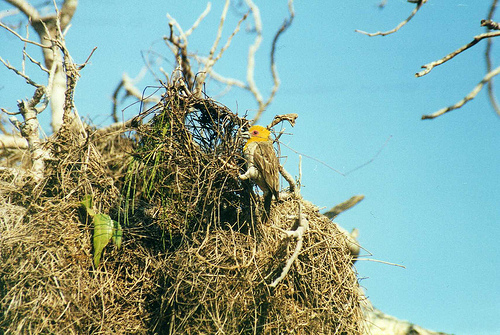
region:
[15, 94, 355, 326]
THAT IS A NEST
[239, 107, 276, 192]
THAT IS A BIRD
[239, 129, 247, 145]
THE BEAK OF THE BIRD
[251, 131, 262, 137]
THE EYE OF THE BIRD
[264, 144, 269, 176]
FEATHERS OF THE BIRD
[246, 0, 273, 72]
A PIECE OF WOOD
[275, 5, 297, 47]
A PIECE OF WOOD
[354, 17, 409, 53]
A PIECE OF WOOD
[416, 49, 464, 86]
A PIECE OF WOOD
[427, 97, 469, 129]
A PIECE OF WOOD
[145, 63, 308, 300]
view is at a bird nest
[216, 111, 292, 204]
bird standing beside the nest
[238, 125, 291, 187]
the bird is brown in color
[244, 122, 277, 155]
the bird has a yelow head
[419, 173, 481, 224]
the sky is clear light blue in color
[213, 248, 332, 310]
the grases are dried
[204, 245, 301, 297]
the grass are brown in color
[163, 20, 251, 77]
the tree branches are dried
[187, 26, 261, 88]
the tree branches are brown in color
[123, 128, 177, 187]
there are green grasses in the dried ones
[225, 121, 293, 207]
bird standing in the grass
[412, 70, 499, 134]
branch with no leaves on it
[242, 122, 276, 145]
bird's head is bright yellow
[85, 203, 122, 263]
bright green leaf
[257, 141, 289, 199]
dark feathers on the body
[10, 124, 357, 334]
a clump of dead grass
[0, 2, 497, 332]
bright blue sky with no clouds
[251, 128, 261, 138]
small black eye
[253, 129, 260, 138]
eye on the side of the head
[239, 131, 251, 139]
small pointy beak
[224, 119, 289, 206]
A yellow bird sits in a nest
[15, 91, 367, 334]
The nest of a bird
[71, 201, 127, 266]
A green leaf in the nest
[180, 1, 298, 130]
A tree stands behind the nest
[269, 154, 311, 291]
A tree branch located in the nest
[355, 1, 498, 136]
Tree branches from a nearby tree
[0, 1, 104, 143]
A tree next to other trees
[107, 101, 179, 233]
Green grass in the nest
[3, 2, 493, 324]
The blue sky above the nest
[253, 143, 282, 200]
The wing of the bird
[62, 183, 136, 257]
leaf on a bunch of grass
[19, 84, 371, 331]
a bunch of weed grass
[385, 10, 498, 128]
tree stick of a tree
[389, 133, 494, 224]
a clear blue sky with no clouds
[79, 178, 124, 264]
some leaves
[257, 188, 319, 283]
tree stick branch on weed grass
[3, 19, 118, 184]
bunch of tree branches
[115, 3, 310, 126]
tree branch sticking out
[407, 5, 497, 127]
crooked tree branch